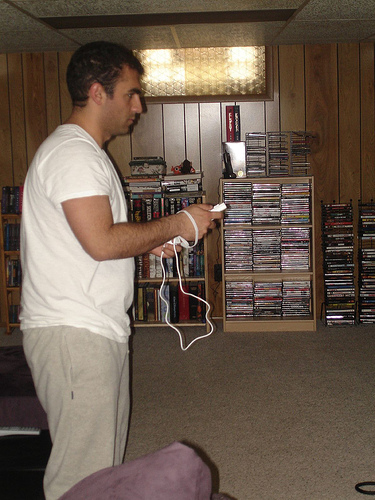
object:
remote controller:
[0, 427, 40, 440]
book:
[132, 196, 142, 223]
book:
[145, 199, 154, 221]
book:
[168, 199, 174, 215]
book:
[137, 288, 144, 322]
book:
[145, 288, 156, 322]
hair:
[65, 39, 147, 110]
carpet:
[0, 316, 375, 499]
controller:
[160, 199, 228, 250]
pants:
[20, 325, 133, 500]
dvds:
[323, 243, 355, 251]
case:
[219, 177, 326, 333]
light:
[130, 44, 267, 99]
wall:
[0, 34, 375, 320]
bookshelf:
[118, 154, 211, 336]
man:
[18, 39, 227, 499]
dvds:
[251, 203, 283, 207]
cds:
[222, 182, 251, 189]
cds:
[224, 279, 252, 287]